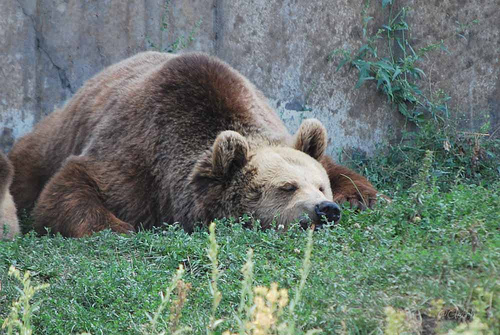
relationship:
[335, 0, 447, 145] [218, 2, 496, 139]
weeds growing on wall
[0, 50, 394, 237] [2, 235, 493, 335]
bear sleeping in grass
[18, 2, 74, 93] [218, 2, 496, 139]
crack in wall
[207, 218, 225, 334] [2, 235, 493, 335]
weeds in grass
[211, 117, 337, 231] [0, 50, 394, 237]
head of bear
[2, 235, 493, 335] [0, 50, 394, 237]
grass underneath bear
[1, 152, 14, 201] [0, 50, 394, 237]
fur beside bear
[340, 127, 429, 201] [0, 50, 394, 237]
weeds behind bear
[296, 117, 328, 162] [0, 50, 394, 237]
ear on bear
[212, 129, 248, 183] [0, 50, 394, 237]
ear on bear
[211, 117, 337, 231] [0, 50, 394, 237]
head of brown bear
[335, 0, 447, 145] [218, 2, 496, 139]
weeds on stone wall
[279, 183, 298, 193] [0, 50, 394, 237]
eye of bear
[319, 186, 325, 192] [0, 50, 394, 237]
left eye of bear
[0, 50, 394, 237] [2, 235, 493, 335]
bear lying in grass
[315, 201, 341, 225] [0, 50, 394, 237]
nose on large bear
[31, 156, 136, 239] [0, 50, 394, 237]
right-leg of bear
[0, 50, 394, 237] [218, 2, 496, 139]
bear in front of wall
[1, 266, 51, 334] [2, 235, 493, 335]
weeds on grass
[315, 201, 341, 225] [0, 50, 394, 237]
nose of bear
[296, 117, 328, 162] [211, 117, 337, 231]
ear on head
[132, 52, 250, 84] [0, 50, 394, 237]
hump on bear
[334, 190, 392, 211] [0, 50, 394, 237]
paw of bear